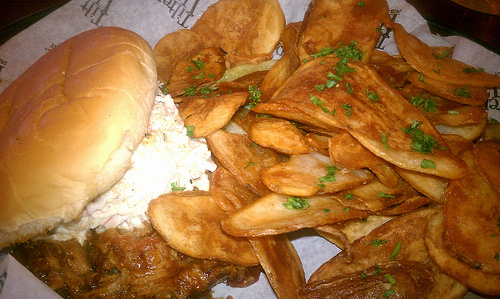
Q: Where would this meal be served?
A: Restaurant.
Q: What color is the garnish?
A: Green.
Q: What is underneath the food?
A: Paper.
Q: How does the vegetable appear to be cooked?
A: Fried.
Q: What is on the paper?
A: Food.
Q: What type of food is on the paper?
A: Sandwich and chips.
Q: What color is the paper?
A: White.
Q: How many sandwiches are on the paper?
A: 1.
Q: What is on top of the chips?
A: Parsley.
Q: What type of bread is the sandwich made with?
A: White hamburger bun.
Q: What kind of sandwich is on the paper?
A: Egg salad sandwich.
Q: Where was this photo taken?
A: Restaurant.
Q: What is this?
A: Bacon.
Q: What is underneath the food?
A: A plastic bag.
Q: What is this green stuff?
A: Parsley.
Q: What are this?
A: Wide slices of potato.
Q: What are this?
A: A pile of potato chips.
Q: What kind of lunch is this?
A: Cheap and unhealthy.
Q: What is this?
A: A pile of food.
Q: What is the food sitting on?
A: Paper.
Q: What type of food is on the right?
A: Fried potatoes.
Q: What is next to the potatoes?
A: Burger.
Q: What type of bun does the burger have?
A: White bread bun.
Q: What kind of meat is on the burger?
A: Bacon.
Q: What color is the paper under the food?
A: White.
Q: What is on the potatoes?
A: Parsley.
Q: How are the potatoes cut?
A: In large slices.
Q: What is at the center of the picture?
A: French fries.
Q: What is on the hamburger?
A: Cole slaw.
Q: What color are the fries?
A: Brown.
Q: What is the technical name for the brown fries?
A: French fries.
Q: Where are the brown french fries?
A: On the plate.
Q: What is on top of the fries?
A: Green topping.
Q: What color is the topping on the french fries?
A: Green.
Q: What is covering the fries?
A: Green topping.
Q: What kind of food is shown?
A: Fast food.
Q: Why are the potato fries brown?
A: They're fried.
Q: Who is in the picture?
A: No one.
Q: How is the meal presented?
A: In a messy fashion.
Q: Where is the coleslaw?
A: On the burger.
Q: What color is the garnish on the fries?
A: Green.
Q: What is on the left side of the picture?
A: A burger.